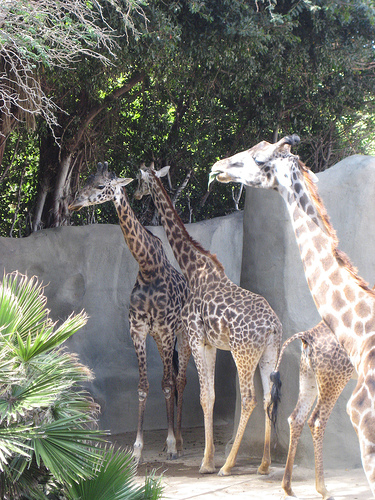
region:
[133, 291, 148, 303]
Dark brown spots of fur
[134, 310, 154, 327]
Dark brown spots of fur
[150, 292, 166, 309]
Dark brown spots of fur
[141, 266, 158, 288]
Dark brown spots of fur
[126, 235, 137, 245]
Dark brown spots of fur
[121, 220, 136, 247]
Dark brown spots of fur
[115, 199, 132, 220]
Dark brown spots of fur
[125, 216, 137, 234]
Dark brown spots of fur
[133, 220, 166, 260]
Dark brown spots of fur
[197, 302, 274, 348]
Dark brown spots of fur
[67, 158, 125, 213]
A giraffes front face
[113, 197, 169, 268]
A giraffes long neck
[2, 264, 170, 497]
Green palm plants small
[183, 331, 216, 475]
A giraffes front leg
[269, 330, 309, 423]
A giraffes hind tail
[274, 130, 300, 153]
The horns of a giraffe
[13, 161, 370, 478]
A group of giraffes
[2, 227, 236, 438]
A stone enclosure wall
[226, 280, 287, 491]
The back side of animal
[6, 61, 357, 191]
Trees hanging high above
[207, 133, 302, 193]
head of a giraffe chewing food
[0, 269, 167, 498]
leaves of a palm tree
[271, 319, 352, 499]
back of a small giraffe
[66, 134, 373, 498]
four giraffes in close proximity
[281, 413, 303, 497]
lower back leg of small giraffe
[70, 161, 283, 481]
two giraffes in the shade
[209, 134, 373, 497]
two giraffes in the sunshine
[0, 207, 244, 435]
a wall behind the giraffes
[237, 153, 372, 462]
a wall on the right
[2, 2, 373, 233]
trees behind the giraffe enclosure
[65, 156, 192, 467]
giraffe with brown spots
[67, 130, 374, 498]
four giraffes standing next to each other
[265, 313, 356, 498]
part of baby giraffe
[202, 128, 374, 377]
head and neck of giraffe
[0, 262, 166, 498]
large green tropical plants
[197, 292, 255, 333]
brown spots on giraffe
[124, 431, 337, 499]
feet of three giraffes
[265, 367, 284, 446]
black tail of giraffe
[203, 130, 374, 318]
giraffe eating a leaf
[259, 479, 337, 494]
two hooves of a giraffe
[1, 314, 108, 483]
tall green palm plant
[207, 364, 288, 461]
black frizzy tail of giraffe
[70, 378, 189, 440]
knees of a giraffe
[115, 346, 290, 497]
giraffe legs and hooves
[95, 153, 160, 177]
two sets of giraffe horns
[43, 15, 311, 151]
green leaves with brown branches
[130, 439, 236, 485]
shadow on the ground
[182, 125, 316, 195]
light on a giraffe head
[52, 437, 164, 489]
part of green palm fronds